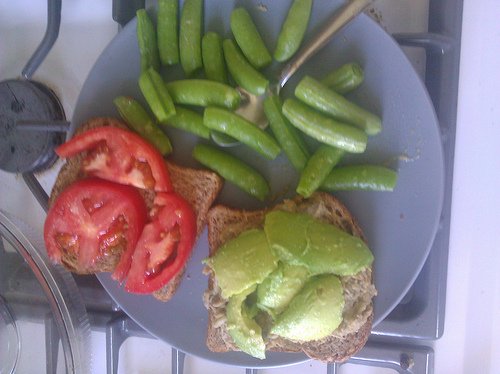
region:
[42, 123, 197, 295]
sliced red tomato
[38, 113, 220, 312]
tomatoes on a piece of bread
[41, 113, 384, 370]
two pieces of bread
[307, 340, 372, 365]
edge of the bread hanging over the plate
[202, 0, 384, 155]
spoon laying on the plate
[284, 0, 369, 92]
silver handle of the spon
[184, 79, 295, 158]
greens laying on the spoon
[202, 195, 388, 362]
green goop on the bread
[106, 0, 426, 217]
greens on the side of the plate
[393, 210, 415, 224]
crumb on the plate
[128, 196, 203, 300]
slice of red tomato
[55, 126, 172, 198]
slice of red tomato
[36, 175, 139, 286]
slice of red tomato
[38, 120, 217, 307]
tomato over slice of bread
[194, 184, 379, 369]
avocado over bread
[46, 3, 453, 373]
vegetables in a dish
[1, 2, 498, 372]
a dish on stove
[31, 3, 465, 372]
a burner under a dish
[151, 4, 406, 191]
green beans on side the dish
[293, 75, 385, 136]
cut green bean on plate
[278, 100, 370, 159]
cut green bean on plate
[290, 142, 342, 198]
cut green bean on plate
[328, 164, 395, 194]
cut green bean on plate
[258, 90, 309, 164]
cut green bean on plate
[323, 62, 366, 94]
cut green bean on plate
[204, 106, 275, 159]
cut green bean on plate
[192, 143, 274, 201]
cut green bean on plate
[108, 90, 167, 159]
cut green bean on plate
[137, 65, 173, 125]
cut green bean on plate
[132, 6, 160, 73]
cut green bean on plate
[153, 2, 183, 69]
cut green bean on plate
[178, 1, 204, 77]
cut green bean on plate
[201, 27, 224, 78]
cut green bean on plate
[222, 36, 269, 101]
cut green bean on plate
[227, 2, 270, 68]
cut green bean on plate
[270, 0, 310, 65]
cut green bean on plate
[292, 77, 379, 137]
cut green bean on plate